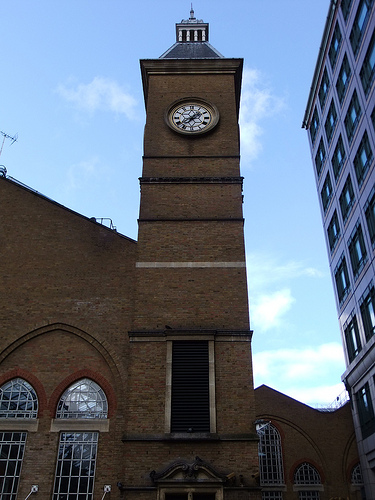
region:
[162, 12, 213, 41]
top of the tower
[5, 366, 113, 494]
windows of the building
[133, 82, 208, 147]
clock on the wall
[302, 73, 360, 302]
windows on the building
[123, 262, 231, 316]
bricks on the wall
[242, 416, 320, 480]
window on the building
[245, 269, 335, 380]
clouds in the sky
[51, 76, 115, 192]
the sky is mostly clear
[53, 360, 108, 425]
reflection on the window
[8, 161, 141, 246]
arch of the roof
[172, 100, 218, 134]
the tower has a clock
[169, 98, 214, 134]
the clock is on the tower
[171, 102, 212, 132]
the clock is high above the street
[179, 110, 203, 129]
the dials are made of metal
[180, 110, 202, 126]
the dials are black in color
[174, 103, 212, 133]
the clock has roman numerals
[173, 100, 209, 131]
the numerals are black in color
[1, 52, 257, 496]
the building is made of brick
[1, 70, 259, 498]
the brick is reddish in color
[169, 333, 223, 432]
the tower has a large window on it's side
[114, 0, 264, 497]
Tower on the building.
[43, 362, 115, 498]
Window on the building.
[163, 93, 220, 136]
clock on the building.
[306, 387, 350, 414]
Railing on the building.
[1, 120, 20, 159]
Antenna on the building.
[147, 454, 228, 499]
Door onthe building.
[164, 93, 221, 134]
Black numbers on the clock.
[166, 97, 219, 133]
White face on the clock.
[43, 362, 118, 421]
Red brick around the building.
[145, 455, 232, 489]
Cement scroll work above the door.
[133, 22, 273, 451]
a giant clock tower of a church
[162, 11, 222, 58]
the slope of a roof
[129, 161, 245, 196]
a ledge on a clock tower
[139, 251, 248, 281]
a white ledge on a clock tower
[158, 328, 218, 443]
a tall black window on a clock tower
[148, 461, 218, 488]
the top design of a window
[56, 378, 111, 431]
a small window on top of a big window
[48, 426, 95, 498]
a big window made up of small windows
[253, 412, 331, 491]
an arched design on a church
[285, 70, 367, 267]
a tall apartment building with windows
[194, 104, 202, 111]
roman numeral on clock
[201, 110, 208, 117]
roman numeral on clock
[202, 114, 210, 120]
roman numeral on clock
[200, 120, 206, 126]
roman numeral on clock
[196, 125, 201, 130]
roman numeral on clock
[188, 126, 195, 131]
roman numeral on clock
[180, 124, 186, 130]
roman numeral on clock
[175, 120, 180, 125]
roman numeral on clock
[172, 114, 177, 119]
roman numeral on clock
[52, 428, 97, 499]
window on a church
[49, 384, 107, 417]
window on a church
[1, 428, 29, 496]
window on a church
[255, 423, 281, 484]
window on a church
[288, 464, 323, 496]
window on a church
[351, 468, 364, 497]
window on a church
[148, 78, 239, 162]
face of the clock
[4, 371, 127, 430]
windows on the building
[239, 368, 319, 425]
top of the building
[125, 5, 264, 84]
top of the building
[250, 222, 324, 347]
sky above the land